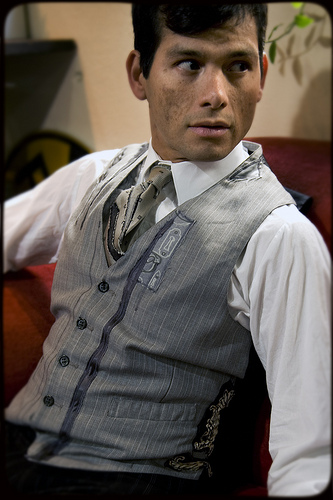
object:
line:
[38, 215, 175, 461]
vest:
[4, 143, 297, 482]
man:
[0, 0, 332, 498]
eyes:
[172, 54, 206, 76]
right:
[256, 0, 328, 150]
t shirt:
[3, 138, 330, 496]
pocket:
[103, 398, 199, 423]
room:
[3, 5, 332, 362]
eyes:
[224, 59, 252, 75]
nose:
[200, 66, 230, 112]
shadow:
[274, 16, 333, 89]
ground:
[265, 96, 301, 121]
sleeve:
[237, 201, 331, 500]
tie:
[101, 160, 178, 270]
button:
[97, 281, 109, 294]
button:
[75, 314, 88, 332]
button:
[58, 352, 70, 369]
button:
[42, 392, 54, 409]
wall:
[1, 4, 332, 157]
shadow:
[289, 68, 333, 146]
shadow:
[43, 48, 93, 155]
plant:
[265, 2, 330, 87]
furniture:
[3, 136, 332, 491]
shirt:
[0, 140, 332, 500]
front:
[13, 142, 295, 478]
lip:
[188, 125, 232, 140]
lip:
[187, 118, 234, 127]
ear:
[125, 49, 149, 103]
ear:
[257, 52, 270, 105]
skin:
[126, 20, 269, 159]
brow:
[167, 43, 200, 57]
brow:
[228, 46, 250, 56]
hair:
[130, 0, 273, 83]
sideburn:
[148, 53, 166, 79]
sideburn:
[256, 49, 263, 76]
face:
[151, 16, 261, 163]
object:
[2, 127, 89, 196]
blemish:
[165, 88, 173, 96]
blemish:
[171, 94, 178, 101]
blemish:
[159, 108, 167, 115]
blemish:
[170, 110, 180, 120]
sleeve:
[244, 210, 331, 495]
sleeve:
[1, 145, 136, 274]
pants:
[1, 422, 210, 498]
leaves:
[292, 11, 315, 32]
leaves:
[290, 0, 301, 11]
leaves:
[267, 39, 278, 68]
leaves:
[265, 21, 283, 43]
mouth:
[185, 118, 232, 140]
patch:
[136, 211, 195, 291]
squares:
[137, 214, 142, 222]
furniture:
[2, 38, 89, 203]